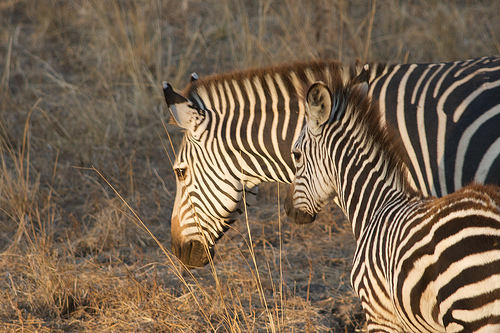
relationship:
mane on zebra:
[176, 53, 349, 95] [162, 57, 498, 272]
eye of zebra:
[170, 145, 219, 196] [150, 52, 416, 328]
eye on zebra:
[289, 146, 309, 170] [285, 77, 497, 332]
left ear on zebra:
[296, 71, 346, 133] [239, 81, 499, 323]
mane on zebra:
[330, 82, 407, 187] [285, 77, 497, 332]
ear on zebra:
[155, 78, 203, 133] [162, 57, 498, 272]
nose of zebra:
[169, 239, 180, 259] [162, 57, 498, 272]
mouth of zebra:
[186, 240, 195, 263] [162, 57, 498, 272]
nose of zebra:
[169, 239, 180, 259] [135, 79, 267, 240]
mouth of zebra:
[179, 237, 211, 267] [135, 79, 267, 240]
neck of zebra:
[212, 73, 314, 197] [162, 57, 498, 272]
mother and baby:
[157, 49, 498, 268] [280, 75, 497, 330]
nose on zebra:
[176, 217, 223, 261] [162, 57, 498, 272]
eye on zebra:
[292, 150, 302, 163] [285, 77, 497, 332]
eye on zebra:
[174, 167, 188, 182] [162, 57, 498, 272]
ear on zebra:
[161, 81, 206, 132] [162, 57, 498, 272]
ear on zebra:
[346, 67, 375, 97] [285, 77, 497, 332]